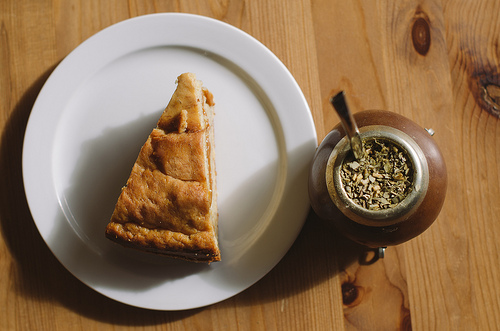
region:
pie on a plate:
[84, 65, 249, 260]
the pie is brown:
[100, 65, 243, 280]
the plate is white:
[7, 12, 330, 324]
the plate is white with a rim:
[13, 18, 317, 320]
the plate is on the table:
[18, 10, 454, 319]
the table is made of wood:
[44, 14, 482, 313]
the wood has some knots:
[399, 4, 499, 116]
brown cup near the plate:
[308, 74, 438, 284]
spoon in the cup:
[307, 80, 393, 171]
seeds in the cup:
[346, 144, 408, 218]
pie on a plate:
[14, 16, 341, 322]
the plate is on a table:
[20, 8, 496, 306]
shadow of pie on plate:
[57, 120, 157, 267]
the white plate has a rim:
[233, 65, 305, 265]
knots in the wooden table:
[401, 9, 451, 79]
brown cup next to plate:
[303, 79, 435, 256]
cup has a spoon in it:
[302, 77, 453, 265]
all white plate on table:
[16, 8, 311, 306]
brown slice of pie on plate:
[108, 70, 220, 258]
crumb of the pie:
[175, 107, 189, 135]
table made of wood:
[355, 2, 497, 92]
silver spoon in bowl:
[329, 89, 370, 154]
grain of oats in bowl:
[350, 143, 409, 200]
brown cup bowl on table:
[323, 81, 450, 264]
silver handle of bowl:
[365, 247, 395, 274]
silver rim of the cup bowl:
[331, 122, 430, 230]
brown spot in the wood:
[407, 7, 442, 67]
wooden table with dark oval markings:
[10, 5, 493, 325]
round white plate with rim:
[20, 11, 312, 311]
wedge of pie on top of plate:
[102, 66, 217, 251]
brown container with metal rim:
[315, 90, 445, 245]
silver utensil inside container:
[325, 80, 365, 165]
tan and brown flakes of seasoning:
[335, 130, 415, 211]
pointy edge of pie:
[161, 65, 201, 142]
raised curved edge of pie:
[105, 211, 217, 261]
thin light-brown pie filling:
[200, 90, 210, 195]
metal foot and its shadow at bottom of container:
[345, 236, 390, 266]